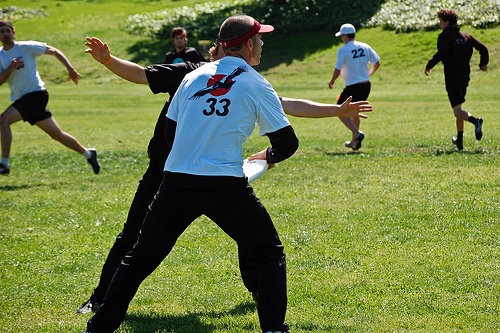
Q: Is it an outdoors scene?
A: Yes, it is outdoors.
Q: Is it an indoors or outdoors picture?
A: It is outdoors.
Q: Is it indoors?
A: No, it is outdoors.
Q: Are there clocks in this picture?
A: No, there are no clocks.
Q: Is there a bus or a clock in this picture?
A: No, there are no clocks or buses.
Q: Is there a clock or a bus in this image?
A: No, there are no clocks or buses.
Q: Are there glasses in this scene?
A: No, there are no glasses.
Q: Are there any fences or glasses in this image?
A: No, there are no glasses or fences.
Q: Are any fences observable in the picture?
A: No, there are no fences.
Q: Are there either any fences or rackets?
A: No, there are no fences or rackets.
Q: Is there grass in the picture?
A: Yes, there is grass.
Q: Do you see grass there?
A: Yes, there is grass.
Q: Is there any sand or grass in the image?
A: Yes, there is grass.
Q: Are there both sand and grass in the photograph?
A: No, there is grass but no sand.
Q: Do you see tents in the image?
A: No, there are no tents.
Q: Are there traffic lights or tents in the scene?
A: No, there are no tents or traffic lights.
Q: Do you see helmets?
A: No, there are no helmets.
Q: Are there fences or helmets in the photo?
A: No, there are no helmets or fences.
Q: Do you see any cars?
A: No, there are no cars.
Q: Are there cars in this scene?
A: No, there are no cars.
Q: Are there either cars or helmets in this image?
A: No, there are no cars or helmets.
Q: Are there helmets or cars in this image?
A: No, there are no cars or helmets.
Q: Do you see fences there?
A: No, there are no fences.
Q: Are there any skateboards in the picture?
A: No, there are no skateboards.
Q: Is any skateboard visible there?
A: No, there are no skateboards.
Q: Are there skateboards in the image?
A: No, there are no skateboards.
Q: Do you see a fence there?
A: No, there are no fences.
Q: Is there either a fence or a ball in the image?
A: No, there are no fences or balls.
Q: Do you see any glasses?
A: No, there are no glasses.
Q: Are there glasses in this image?
A: No, there are no glasses.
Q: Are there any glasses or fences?
A: No, there are no glasses or fences.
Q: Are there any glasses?
A: No, there are no glasses.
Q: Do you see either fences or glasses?
A: No, there are no glasses or fences.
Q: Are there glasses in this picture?
A: No, there are no glasses.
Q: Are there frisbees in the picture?
A: Yes, there is a frisbee.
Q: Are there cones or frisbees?
A: Yes, there is a frisbee.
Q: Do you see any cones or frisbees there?
A: Yes, there is a frisbee.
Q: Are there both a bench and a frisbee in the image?
A: No, there is a frisbee but no benches.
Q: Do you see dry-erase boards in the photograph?
A: No, there are no dry-erase boards.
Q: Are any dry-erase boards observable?
A: No, there are no dry-erase boards.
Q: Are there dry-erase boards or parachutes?
A: No, there are no dry-erase boards or parachutes.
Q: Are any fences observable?
A: No, there are no fences.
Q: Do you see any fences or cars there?
A: No, there are no fences or cars.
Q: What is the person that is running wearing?
A: The person is wearing shorts.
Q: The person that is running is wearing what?
A: The person is wearing shorts.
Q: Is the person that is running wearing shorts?
A: Yes, the person is wearing shorts.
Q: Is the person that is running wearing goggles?
A: No, the person is wearing shorts.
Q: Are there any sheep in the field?
A: No, there is a person in the field.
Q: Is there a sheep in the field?
A: No, there is a person in the field.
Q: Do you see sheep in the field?
A: No, there is a person in the field.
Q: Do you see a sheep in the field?
A: No, there is a person in the field.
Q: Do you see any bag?
A: No, there are no bags.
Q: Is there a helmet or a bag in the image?
A: No, there are no bags or helmets.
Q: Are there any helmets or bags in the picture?
A: No, there are no bags or helmets.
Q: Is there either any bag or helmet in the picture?
A: No, there are no bags or helmets.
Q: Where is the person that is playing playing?
A: The person is playing on the field.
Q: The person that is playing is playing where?
A: The person is playing on the field.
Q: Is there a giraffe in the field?
A: No, there is a person in the field.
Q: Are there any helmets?
A: No, there are no helmets.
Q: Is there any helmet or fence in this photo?
A: No, there are no helmets or fences.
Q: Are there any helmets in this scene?
A: No, there are no helmets.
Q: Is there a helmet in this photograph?
A: No, there are no helmets.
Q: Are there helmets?
A: No, there are no helmets.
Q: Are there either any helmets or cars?
A: No, there are no helmets or cars.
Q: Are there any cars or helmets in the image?
A: No, there are no helmets or cars.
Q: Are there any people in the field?
A: Yes, there is a person in the field.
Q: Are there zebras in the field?
A: No, there is a person in the field.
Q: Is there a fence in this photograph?
A: No, there are no fences.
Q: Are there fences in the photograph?
A: No, there are no fences.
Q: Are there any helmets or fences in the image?
A: No, there are no fences or helmets.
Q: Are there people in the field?
A: Yes, there is a person in the field.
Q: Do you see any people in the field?
A: Yes, there is a person in the field.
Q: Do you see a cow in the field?
A: No, there is a person in the field.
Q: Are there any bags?
A: No, there are no bags.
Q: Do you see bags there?
A: No, there are no bags.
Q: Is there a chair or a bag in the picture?
A: No, there are no bags or chairs.